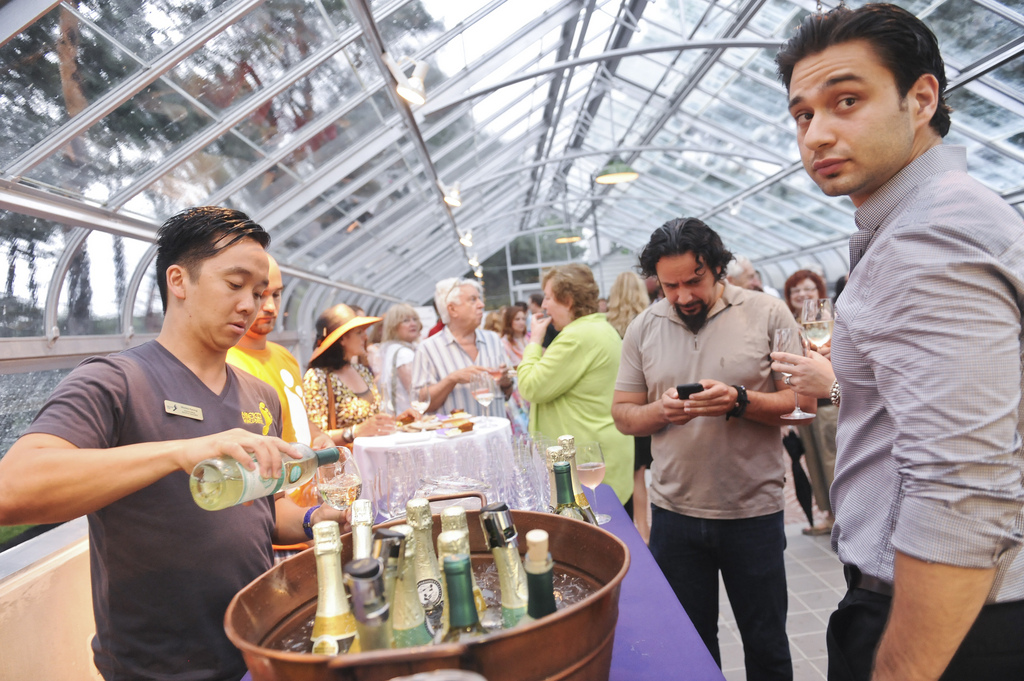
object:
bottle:
[191, 444, 341, 513]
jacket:
[514, 310, 635, 508]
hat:
[309, 303, 385, 363]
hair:
[154, 205, 267, 309]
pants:
[649, 508, 791, 680]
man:
[0, 207, 350, 677]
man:
[413, 277, 515, 419]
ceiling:
[0, 4, 1022, 339]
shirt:
[224, 336, 312, 467]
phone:
[677, 382, 705, 400]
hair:
[381, 298, 422, 342]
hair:
[545, 263, 600, 317]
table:
[353, 397, 548, 524]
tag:
[164, 400, 203, 422]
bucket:
[221, 497, 626, 680]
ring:
[785, 376, 796, 386]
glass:
[314, 446, 363, 512]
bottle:
[436, 530, 477, 628]